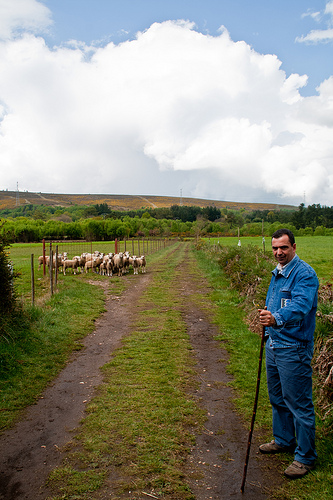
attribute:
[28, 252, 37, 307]
fence post — metal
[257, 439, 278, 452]
shoe — brown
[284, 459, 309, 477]
shoe — brown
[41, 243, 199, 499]
grass — green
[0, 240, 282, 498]
dirt — brown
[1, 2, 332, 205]
clouds — white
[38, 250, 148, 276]
animals — white, furry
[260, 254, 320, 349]
shirt — blue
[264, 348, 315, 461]
pants — blue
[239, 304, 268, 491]
stick — large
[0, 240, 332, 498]
road — grassy, dirt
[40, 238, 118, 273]
gate — open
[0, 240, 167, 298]
field — green, grassy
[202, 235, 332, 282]
field — grassy, green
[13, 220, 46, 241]
tree — leafy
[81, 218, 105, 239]
tree — leafy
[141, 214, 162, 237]
tree — leafy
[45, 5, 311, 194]
sky — cloudy, blue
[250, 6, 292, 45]
sky — blue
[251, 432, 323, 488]
shoes — brown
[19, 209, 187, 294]
fence — long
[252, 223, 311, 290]
man — blue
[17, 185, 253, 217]
hill — large